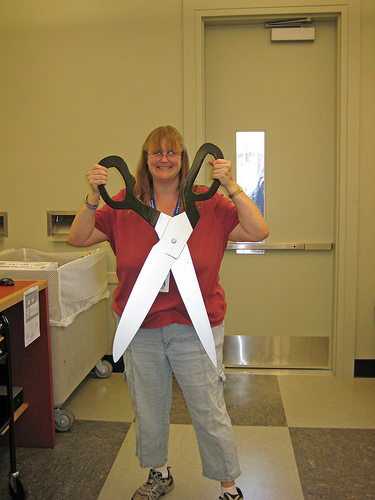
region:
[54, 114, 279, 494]
woman holding a large pair of novelty shears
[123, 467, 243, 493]
woman wearing sneakers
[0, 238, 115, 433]
large bin with wheels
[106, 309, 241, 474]
woman wearing light grey pants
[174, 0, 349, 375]
tall door behind woman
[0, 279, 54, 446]
wooden desk with low shelf inside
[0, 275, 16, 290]
black computer mouse on desk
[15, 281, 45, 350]
paper hanging from edge of desk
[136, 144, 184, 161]
woman is wearing glasses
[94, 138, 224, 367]
Large scissor with metal blades.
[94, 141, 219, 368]
Scissor with black handles.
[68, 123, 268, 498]
Woman holding a large scissor.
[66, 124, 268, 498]
Woman holding the handles of scissor.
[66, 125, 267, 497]
Woman wearing eyeglasses holding a black handled scissor.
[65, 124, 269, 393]
Employee holding a big pair of scissors.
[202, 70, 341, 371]
Door to a room.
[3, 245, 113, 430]
Large bin containing supplies.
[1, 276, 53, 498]
Wooden table with paper taped to the edge.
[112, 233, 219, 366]
Metal blades on the scissor.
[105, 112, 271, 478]
woman holding giant scissors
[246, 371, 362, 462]
black and white square patterned floor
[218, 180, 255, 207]
watch on woman's right wrist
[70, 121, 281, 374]
woman wearing glasses on her face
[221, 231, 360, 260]
silver emergency bar of door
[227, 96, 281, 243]
small window to look out door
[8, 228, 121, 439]
large white bin on wheels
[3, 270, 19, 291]
black mouse on desk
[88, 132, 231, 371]
giant silver and black scissors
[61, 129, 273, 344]
woman in red shirt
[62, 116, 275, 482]
The woman is holding an oversized pair of scissors.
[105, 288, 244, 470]
The woman is wearing jeans.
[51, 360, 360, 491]
The floor has a checkerboard pattern.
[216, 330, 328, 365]
A metal panel on the door.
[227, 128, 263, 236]
A small rectangular window.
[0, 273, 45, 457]
A wooden desk.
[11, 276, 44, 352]
A piece of paper attached to the desk.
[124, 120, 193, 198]
The woman has light brown hair.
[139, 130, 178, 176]
The woman is wearing glasses.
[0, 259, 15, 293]
A computer mouse.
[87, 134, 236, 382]
the scissors are big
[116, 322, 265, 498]
the pants are gray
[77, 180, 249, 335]
the shirt is red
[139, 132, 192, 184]
the woman has glasses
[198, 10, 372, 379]
the door is white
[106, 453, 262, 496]
the girl has shoes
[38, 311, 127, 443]
the bin has wheels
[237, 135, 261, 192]
it is daytime outside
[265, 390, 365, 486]
the floor is black and white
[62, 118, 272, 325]
the woman is white